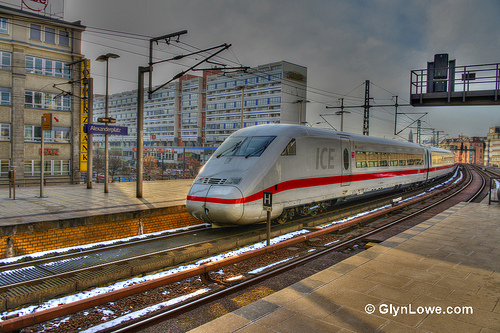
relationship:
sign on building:
[76, 57, 93, 172] [3, 2, 93, 187]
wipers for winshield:
[219, 116, 249, 188] [204, 117, 285, 173]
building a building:
[0, 2, 93, 188] [177, 75, 319, 172]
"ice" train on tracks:
[313, 144, 338, 169] [7, 243, 399, 327]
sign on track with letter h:
[257, 189, 277, 243] [228, 169, 283, 279]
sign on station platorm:
[87, 91, 161, 179] [33, 124, 203, 239]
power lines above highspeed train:
[123, 33, 296, 103] [170, 116, 470, 223]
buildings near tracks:
[86, 57, 290, 162] [53, 172, 488, 269]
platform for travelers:
[182, 202, 498, 332] [39, 146, 97, 273]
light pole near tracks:
[104, 48, 111, 197] [0, 167, 499, 332]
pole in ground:
[38, 115, 44, 196] [2, 178, 498, 331]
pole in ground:
[104, 56, 109, 194] [2, 178, 498, 331]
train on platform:
[185, 120, 463, 228] [407, 52, 499, 112]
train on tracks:
[185, 120, 463, 228] [7, 208, 391, 322]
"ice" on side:
[313, 144, 338, 169] [297, 133, 454, 195]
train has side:
[185, 120, 463, 228] [297, 133, 454, 195]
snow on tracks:
[106, 252, 224, 282] [0, 165, 485, 332]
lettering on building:
[79, 58, 94, 170] [3, 2, 93, 187]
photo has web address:
[1, 1, 498, 330] [361, 298, 478, 321]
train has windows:
[185, 120, 463, 228] [348, 144, 427, 174]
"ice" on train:
[313, 144, 338, 169] [182, 107, 480, 231]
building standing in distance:
[437, 135, 484, 164] [314, 78, 484, 166]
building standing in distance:
[481, 125, 484, 164] [314, 78, 484, 166]